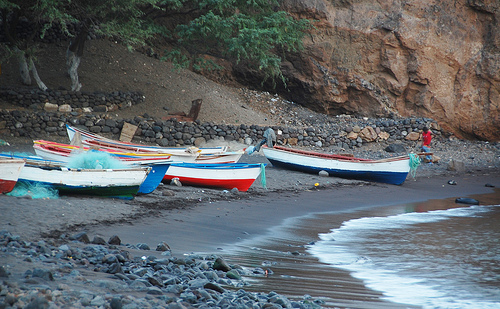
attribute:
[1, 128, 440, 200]
boats — red, white, blue, standing, sitting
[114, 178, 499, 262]
shore — wet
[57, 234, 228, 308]
rocks — gray, wet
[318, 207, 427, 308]
foam — white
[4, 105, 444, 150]
wall — stone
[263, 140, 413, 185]
boat — white, wood, blue, red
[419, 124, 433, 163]
person — standing, walking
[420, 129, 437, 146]
shirt — red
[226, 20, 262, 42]
leaves — healthy, green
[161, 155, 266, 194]
boat — red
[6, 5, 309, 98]
trees — green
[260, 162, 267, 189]
fabric — blue, hanging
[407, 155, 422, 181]
string — hanging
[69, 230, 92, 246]
rock — brown, black, laying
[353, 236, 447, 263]
water — white, brown